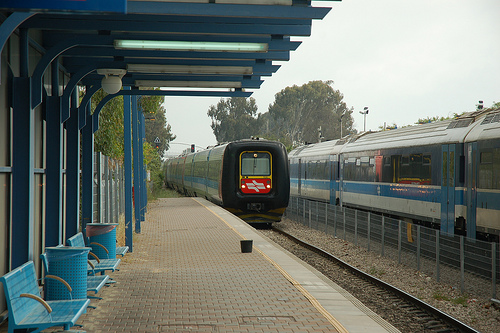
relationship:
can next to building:
[45, 248, 90, 299] [4, 1, 337, 329]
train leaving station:
[182, 127, 280, 224] [45, 28, 455, 330]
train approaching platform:
[160, 134, 293, 229] [9, 188, 407, 331]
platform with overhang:
[4, 0, 396, 330] [4, 0, 334, 100]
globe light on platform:
[100, 74, 121, 96] [4, 0, 396, 330]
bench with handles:
[2, 228, 128, 331] [17, 240, 107, 312]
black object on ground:
[238, 238, 255, 254] [152, 196, 199, 328]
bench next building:
[5, 228, 127, 331] [0, 5, 164, 330]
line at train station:
[233, 247, 317, 304] [2, 7, 477, 330]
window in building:
[32, 171, 46, 258] [0, 9, 100, 320]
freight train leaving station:
[268, 100, 500, 244] [0, 0, 498, 331]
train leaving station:
[160, 134, 293, 229] [0, 0, 498, 331]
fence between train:
[268, 195, 500, 303] [160, 134, 293, 229]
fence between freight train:
[268, 195, 500, 303] [268, 100, 500, 244]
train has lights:
[160, 134, 293, 229] [236, 181, 275, 194]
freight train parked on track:
[268, 103, 498, 244] [300, 210, 495, 280]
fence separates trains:
[246, 163, 491, 319] [202, 105, 497, 284]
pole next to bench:
[121, 85, 133, 250] [0, 263, 90, 331]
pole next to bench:
[121, 85, 133, 250] [42, 243, 109, 327]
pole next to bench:
[121, 85, 133, 250] [65, 231, 120, 300]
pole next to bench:
[121, 85, 133, 250] [83, 225, 129, 280]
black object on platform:
[231, 232, 255, 260] [157, 199, 227, 324]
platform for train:
[3, 172, 396, 332] [153, 137, 291, 225]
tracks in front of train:
[263, 226, 488, 332] [160, 134, 293, 229]